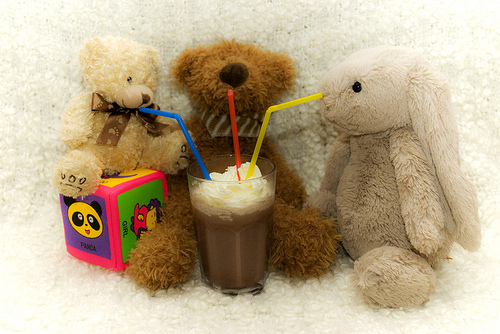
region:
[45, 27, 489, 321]
three stuffed animals pretending to drink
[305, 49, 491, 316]
a light brown bunny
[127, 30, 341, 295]
a brown bear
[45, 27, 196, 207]
a light brown bear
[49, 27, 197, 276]
a bear sitting on toy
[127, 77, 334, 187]
three colorful straws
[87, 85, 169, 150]
a brown ribbon with paw prints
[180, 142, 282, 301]
a brown drink in a glass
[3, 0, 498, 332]
behind the toys is a white blanket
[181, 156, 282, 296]
white whipped cream floats on drink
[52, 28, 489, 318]
Three stuffed animals pretending to drink chocolate milkshake.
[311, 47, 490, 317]
A tan stuffed rabbit.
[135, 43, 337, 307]
A brown stuffed teddy bear.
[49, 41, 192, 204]
A little beige stuffed teddy bear.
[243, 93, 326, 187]
Yellow straw for stuffed rabbit.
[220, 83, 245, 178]
Red plastic straw for brown stuffed teddy bear.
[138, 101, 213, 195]
Blue plastic straw for little beige stuffed teddy bear.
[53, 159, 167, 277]
A pink, purple, yellow and green stuffed block.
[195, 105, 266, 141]
Brown teddy bear wearing brown and white striped kerchief around neck.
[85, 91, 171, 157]
Little beige teddy bear wearing brown ribbon around neck.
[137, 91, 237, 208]
Blue straw going into glass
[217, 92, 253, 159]
Red straw going into glass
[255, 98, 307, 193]
Yellow straw going into glass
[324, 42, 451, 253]
Rabbit stuffed animal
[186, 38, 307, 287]
Bear stuffed animal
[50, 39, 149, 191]
Bear stuffed animal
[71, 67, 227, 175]
Bear is wearing bow around neck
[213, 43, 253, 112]
Brown nose on bear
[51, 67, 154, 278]
Little bear is sitting on block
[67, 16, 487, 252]
Three stuffed animals next to each other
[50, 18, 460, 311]
three teddy bear sipping drink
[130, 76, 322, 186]
three plastic straws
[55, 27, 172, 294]
teddy bear sitting on top of block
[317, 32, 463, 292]
stuffed rabbit with long ears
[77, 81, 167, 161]
brown bow around teddy bears neck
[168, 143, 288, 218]
white whipped cream on top of drink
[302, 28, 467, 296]
stuffed rabbit with black eyes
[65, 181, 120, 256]
panda bear on toy block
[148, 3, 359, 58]
white blanket used as background for photo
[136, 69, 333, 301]
ice cream float drink with whipped cream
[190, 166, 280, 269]
Yummy chocolate milkshake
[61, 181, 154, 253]
Toy block with panda and girl on it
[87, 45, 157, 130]
Light blonde teddy bear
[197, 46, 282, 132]
Brown teddy bear with striped scarf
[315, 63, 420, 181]
White rabbit toy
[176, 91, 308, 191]
Three friends sharing a milkshake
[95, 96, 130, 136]
Brown bow on light blonde bear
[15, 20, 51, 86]
Fluffy white background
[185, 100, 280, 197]
Colorful straws (red, blue, and yellow)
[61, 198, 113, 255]
Colorful block with panda